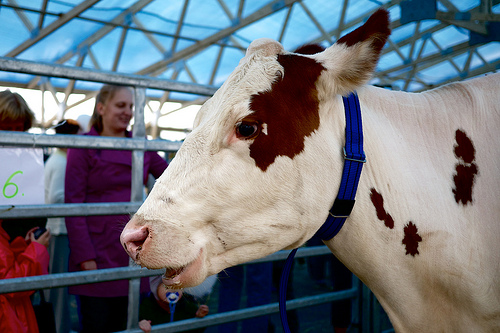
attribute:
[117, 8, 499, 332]
cow — white, brown, still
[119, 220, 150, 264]
nose — pink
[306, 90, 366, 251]
collar — blue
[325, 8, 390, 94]
ear — backwards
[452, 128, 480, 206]
spots — brown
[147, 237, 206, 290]
mouth — open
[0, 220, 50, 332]
coat — red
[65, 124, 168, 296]
coat — purple, wearing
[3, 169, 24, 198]
number — green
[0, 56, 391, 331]
gate — silver, gray, metal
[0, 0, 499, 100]
ceiling — blue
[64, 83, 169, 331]
woman — smiling